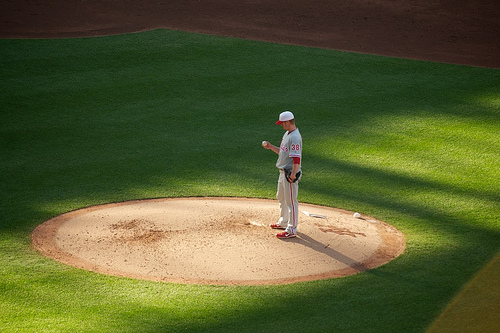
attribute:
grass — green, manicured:
[5, 25, 499, 331]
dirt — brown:
[1, 1, 500, 71]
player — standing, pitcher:
[265, 109, 301, 242]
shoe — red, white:
[277, 230, 293, 239]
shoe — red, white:
[272, 221, 281, 229]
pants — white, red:
[275, 172, 298, 229]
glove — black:
[284, 168, 302, 183]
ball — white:
[260, 141, 270, 147]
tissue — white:
[355, 211, 360, 218]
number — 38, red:
[294, 143, 302, 152]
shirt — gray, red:
[276, 130, 301, 176]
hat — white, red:
[276, 111, 295, 127]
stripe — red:
[289, 181, 299, 231]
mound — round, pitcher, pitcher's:
[30, 197, 408, 287]